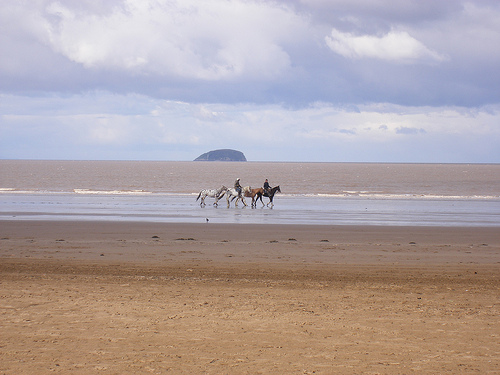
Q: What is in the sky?
A: Clouds.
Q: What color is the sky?
A: Blue.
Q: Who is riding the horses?
A: Two people.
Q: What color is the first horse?
A: Brown.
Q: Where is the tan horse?
A: Middle.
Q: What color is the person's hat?
A: White.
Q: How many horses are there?
A: Three.